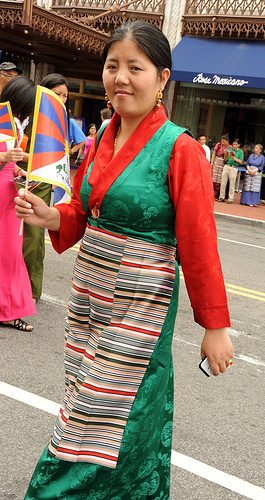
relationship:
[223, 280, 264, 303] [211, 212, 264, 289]
yellow lines dividing road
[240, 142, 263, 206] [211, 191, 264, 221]
people standing sidewalk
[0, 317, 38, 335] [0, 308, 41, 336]
sandal on foot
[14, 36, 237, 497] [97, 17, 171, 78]
girl has dark hair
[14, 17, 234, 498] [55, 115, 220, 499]
girl has dress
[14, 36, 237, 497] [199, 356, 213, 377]
girl carries cell phone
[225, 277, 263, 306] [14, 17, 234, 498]
line behind girl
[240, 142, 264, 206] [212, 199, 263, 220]
people standing on sidewalk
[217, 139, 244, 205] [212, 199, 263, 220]
people standing on sidewalk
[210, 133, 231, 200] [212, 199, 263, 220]
people standing on sidewalk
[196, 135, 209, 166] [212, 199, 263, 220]
people standing on sidewalk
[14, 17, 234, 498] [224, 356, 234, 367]
girl wearing ring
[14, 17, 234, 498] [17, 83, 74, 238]
girl holding flag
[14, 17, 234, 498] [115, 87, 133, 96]
girl has mouth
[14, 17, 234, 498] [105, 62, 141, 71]
girl has eyes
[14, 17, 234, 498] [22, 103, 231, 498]
girl in dress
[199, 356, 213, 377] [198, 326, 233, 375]
cell phone in hand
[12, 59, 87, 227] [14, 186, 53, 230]
flag in hand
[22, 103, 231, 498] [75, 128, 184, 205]
dress with striped front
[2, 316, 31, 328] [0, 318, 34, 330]
foot wearing sandal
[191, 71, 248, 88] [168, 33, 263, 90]
lettering on awning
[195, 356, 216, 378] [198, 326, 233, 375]
cell phone in hand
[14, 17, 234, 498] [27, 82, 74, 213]
girl with flag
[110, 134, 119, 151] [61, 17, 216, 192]
necklace on woman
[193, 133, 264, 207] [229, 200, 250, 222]
pedestrians on sidewalk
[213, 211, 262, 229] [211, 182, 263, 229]
curb on sidewalk